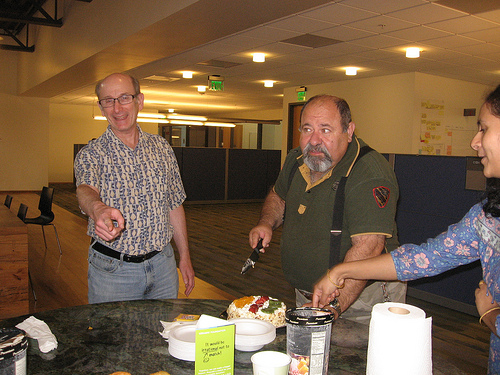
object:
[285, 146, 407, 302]
suspenders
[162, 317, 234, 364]
plates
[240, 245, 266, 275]
knife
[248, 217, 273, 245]
hand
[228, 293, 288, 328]
cake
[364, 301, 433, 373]
bowls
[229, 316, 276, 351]
bowls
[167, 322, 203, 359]
bowls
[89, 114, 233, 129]
flourescent light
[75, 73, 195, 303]
man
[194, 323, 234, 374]
green sign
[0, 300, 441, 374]
table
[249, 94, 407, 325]
man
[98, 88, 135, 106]
glasses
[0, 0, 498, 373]
room